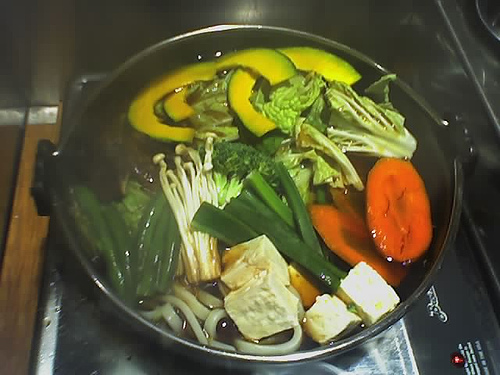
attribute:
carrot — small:
[325, 179, 366, 220]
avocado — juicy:
[225, 41, 361, 132]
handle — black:
[22, 133, 57, 229]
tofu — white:
[209, 235, 404, 350]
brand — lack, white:
[418, 277, 450, 329]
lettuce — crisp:
[287, 82, 418, 164]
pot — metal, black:
[32, 20, 474, 368]